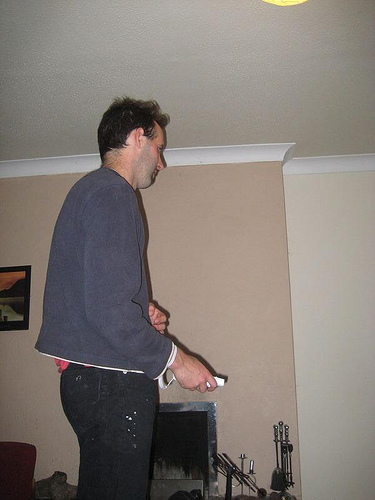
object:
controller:
[203, 367, 228, 394]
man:
[28, 87, 222, 500]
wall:
[0, 161, 300, 495]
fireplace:
[150, 392, 225, 495]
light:
[260, 0, 324, 16]